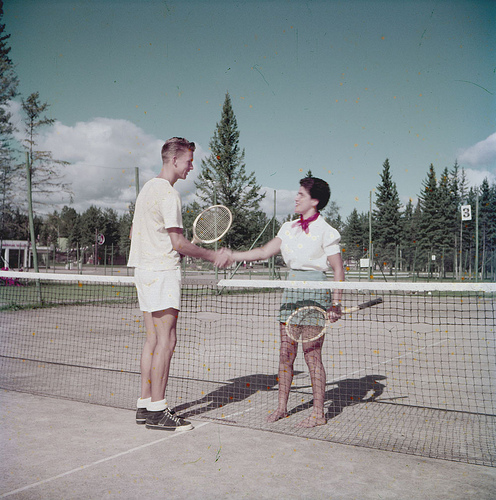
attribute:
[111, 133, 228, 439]
man — shaking hands, with white shirt, with white shorts, with black shoes, with tennis racket, with tennis shoes, a tennis player, standing on net, holding racket, with short hair, with blond hair, wearing white tshirt, wearing white shorts, wearing white socks, wearing black shoes, holding tennis racke, playing badminton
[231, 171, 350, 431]
lady — playing tennis, with scarf, bare foot, with tennis racket, with blue skirt, with red scarf, holding a racket, with short hair, wearing blue skirt, wearing white tshirt, with white scarf, with brown hair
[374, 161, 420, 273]
pine tree — against sky, very tall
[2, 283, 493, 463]
tennis net — long, black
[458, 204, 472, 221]
sign — with number 3